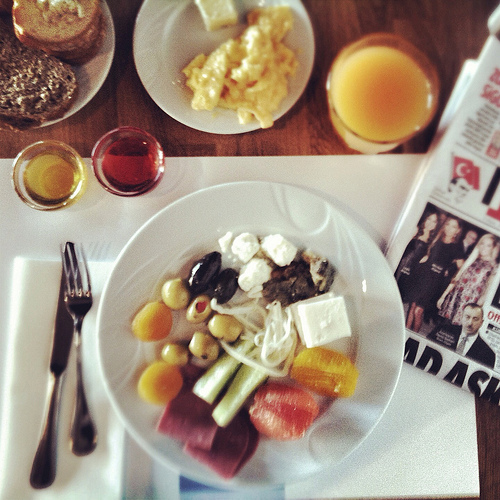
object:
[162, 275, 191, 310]
olive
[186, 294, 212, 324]
olive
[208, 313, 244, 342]
olive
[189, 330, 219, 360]
olive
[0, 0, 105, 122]
toast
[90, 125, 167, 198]
cup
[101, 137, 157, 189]
liquid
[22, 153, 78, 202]
liquid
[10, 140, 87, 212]
cup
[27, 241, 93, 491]
silverware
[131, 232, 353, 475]
food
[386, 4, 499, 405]
newspaper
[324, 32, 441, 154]
orange juice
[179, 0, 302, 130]
eggs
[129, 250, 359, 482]
fruit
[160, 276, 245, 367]
olives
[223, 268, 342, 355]
food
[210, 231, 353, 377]
feta cheese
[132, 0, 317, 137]
plate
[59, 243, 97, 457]
fork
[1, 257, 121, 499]
napkin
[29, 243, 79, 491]
knife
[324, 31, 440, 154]
glass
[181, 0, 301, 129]
food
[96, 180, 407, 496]
plate